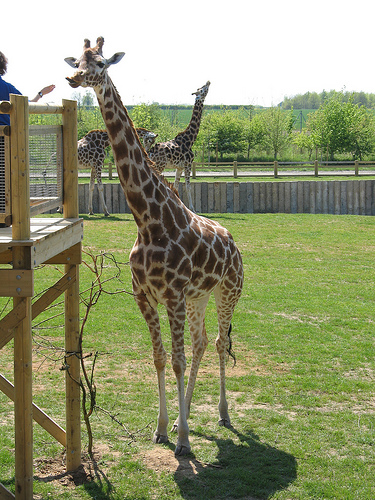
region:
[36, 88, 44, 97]
watch on woman's wrist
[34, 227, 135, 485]
dead vine on wooden bridge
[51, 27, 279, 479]
Giraffe reaching for woman's treat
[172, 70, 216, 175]
Giraffe looking to sky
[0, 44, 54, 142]
woman wearing blue shirt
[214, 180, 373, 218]
retaining wall made of logs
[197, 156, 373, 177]
fence made of wood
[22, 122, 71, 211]
metal mesh grating on bridge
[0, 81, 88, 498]
petting bridge made of logs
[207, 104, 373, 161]
low growing trees in background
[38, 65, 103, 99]
Giraffe about to be fed by a woman.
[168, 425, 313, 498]
The giraffe's shadow on the ground.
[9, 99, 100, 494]
Platform the woman is standing on.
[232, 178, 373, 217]
Wooden fence in the background.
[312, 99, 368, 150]
The leaves on the tree are green.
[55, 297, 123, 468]
Branch growing by the platform.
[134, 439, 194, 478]
Bare spot in the grass.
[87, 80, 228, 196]
Two giraffes in the background.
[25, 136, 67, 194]
The wall is made of wire.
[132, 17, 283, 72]
The sky is white.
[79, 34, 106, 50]
horns of a giraffe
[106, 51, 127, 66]
ear of a giraffe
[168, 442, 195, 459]
hoof of a giraffe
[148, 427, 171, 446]
hoof of a giraffe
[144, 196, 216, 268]
spots on a giraffe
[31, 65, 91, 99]
hand and a giraffe's nose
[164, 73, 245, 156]
giraffe stretching it's neck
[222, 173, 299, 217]
a wooden plank fence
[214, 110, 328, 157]
three trees in a row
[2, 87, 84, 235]
railing on a platform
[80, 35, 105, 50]
The giraffe's ossicones that sit atop it's head.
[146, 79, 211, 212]
Tall giraffe in the back holding it's head straight up.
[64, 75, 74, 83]
Small black giraffe tongue.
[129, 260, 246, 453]
Four legs on the closest giraffe.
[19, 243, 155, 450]
Tall thin leafless tree in front of the closest giraffe.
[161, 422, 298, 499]
Shadow of the closest giraffe.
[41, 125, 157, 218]
Giraffe in the back with its head down on another giraffe.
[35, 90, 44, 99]
Watch on a persons right wrist.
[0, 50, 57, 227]
A woman standing on a platform.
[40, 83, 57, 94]
Right hand of a woman standing above the giraffes.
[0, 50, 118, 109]
a woman feeding a giraffe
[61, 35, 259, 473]
three giraffes at a zoo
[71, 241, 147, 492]
a branch attached to wood platform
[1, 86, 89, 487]
wood platform to feed animals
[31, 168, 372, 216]
a wooden fence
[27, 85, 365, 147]
a green field surrounded by trees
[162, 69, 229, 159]
a giraffe looking up into the air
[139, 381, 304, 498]
shadow of a giraffe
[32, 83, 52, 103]
a watch on a womans wrist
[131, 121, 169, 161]
giraffe rubbing head on giraffes butt